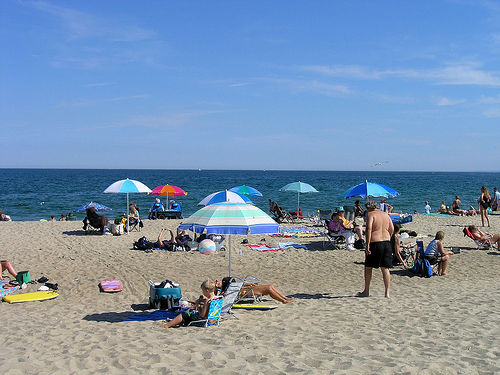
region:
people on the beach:
[1, 170, 498, 335]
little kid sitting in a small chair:
[162, 280, 228, 333]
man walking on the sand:
[356, 204, 391, 305]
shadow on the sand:
[286, 286, 354, 301]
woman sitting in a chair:
[414, 223, 454, 279]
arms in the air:
[156, 226, 176, 243]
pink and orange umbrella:
[151, 181, 189, 208]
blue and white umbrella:
[103, 173, 146, 232]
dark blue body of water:
[0, 168, 498, 223]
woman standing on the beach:
[478, 185, 493, 230]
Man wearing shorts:
[364, 239, 395, 269]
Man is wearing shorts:
[358, 238, 402, 270]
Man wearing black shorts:
[365, 235, 397, 269]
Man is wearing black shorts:
[362, 238, 394, 269]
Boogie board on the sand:
[3, 285, 60, 307]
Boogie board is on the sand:
[0, 287, 62, 307]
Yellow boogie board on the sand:
[2, 286, 62, 308]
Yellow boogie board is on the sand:
[0, 287, 63, 306]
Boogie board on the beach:
[0, 284, 62, 306]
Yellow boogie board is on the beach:
[2, 286, 64, 305]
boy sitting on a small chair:
[164, 278, 222, 330]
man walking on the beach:
[352, 199, 397, 300]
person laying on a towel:
[148, 224, 183, 259]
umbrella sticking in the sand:
[181, 200, 276, 292]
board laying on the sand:
[98, 276, 124, 298]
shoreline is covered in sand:
[1, 220, 498, 374]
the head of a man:
[354, 182, 401, 214]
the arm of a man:
[346, 191, 390, 257]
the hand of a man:
[353, 242, 383, 269]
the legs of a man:
[346, 249, 433, 307]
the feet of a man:
[334, 255, 461, 305]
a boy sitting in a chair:
[162, 253, 259, 345]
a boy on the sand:
[138, 278, 254, 351]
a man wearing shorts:
[333, 240, 418, 297]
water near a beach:
[55, 128, 250, 248]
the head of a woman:
[433, 228, 453, 253]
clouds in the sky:
[276, 50, 494, 117]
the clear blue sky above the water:
[38, 26, 339, 133]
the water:
[13, 163, 490, 208]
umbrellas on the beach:
[84, 183, 449, 278]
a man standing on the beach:
[361, 200, 399, 302]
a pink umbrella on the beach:
[153, 184, 183, 193]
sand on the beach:
[261, 314, 496, 356]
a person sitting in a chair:
[420, 233, 468, 281]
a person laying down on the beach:
[202, 275, 297, 315]